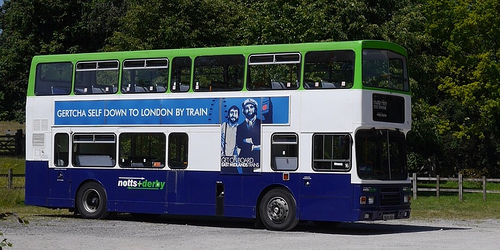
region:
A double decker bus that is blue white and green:
[17, 37, 426, 249]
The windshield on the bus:
[351, 126, 413, 223]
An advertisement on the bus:
[55, 97, 280, 127]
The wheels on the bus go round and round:
[76, 177, 300, 227]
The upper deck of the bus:
[34, 57, 408, 94]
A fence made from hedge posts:
[410, 162, 498, 203]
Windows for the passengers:
[53, 127, 190, 181]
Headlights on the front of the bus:
[361, 183, 408, 219]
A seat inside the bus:
[74, 154, 113, 171]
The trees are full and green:
[418, 4, 490, 151]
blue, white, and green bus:
[19, 41, 424, 221]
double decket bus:
[22, 42, 415, 223]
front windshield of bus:
[350, 125, 405, 175]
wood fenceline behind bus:
[1, 159, 497, 206]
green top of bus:
[23, 40, 406, 92]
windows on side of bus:
[37, 60, 349, 173]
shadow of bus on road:
[291, 201, 445, 241]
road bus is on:
[13, 209, 497, 249]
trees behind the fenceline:
[8, 3, 496, 151]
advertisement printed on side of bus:
[53, 103, 284, 168]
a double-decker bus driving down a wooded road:
[15, 33, 420, 237]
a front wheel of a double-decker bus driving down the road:
[255, 186, 305, 233]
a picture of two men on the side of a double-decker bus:
[218, 98, 265, 172]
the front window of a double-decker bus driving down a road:
[352, 122, 417, 184]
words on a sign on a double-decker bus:
[50, 93, 223, 129]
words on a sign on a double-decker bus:
[105, 172, 170, 196]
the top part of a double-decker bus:
[20, 36, 417, 99]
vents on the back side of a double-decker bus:
[25, 113, 55, 155]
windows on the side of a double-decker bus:
[47, 126, 198, 173]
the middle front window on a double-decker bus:
[365, 91, 417, 128]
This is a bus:
[22, 45, 279, 236]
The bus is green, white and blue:
[56, 67, 366, 245]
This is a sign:
[35, 98, 192, 135]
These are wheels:
[77, 180, 298, 224]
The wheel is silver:
[265, 194, 290, 209]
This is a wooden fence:
[431, 165, 496, 200]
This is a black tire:
[240, 187, 280, 232]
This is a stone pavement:
[61, 225, 117, 245]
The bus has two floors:
[112, 84, 412, 245]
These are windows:
[207, 52, 257, 88]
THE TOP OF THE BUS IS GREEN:
[18, 37, 413, 102]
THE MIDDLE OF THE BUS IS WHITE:
[20, 89, 414, 189]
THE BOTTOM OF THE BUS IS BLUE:
[15, 152, 419, 238]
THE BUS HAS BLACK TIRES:
[65, 174, 305, 233]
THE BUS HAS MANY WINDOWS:
[30, 45, 410, 185]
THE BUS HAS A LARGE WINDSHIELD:
[349, 123, 424, 192]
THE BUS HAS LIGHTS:
[356, 189, 416, 214]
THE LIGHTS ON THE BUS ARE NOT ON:
[349, 188, 416, 220]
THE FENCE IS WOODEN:
[0, 164, 498, 206]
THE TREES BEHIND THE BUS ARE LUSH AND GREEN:
[2, 2, 497, 190]